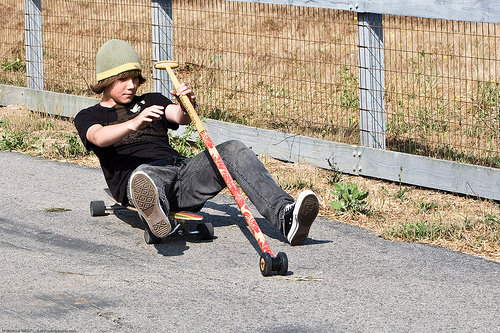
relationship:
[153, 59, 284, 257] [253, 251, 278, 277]
pole has wheel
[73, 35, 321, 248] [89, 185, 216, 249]
guy sitting on skateboard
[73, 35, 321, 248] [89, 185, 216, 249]
guy on top of skateboard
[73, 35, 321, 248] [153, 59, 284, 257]
guy holding pole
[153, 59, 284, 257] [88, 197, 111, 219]
pole has wheel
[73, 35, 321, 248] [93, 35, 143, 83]
guy wearing cap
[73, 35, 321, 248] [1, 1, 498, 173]
guy beside fencing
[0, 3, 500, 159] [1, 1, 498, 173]
grass beside fencing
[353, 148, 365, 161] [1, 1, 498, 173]
bolt holding fencing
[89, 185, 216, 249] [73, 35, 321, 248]
skateboard under guy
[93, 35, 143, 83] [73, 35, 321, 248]
cap worn on guy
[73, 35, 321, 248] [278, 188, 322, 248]
guy has sneaker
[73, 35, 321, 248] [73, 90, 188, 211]
guy has t-shirt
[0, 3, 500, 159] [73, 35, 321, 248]
grass near guy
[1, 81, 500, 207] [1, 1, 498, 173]
wood on bottom of fencing